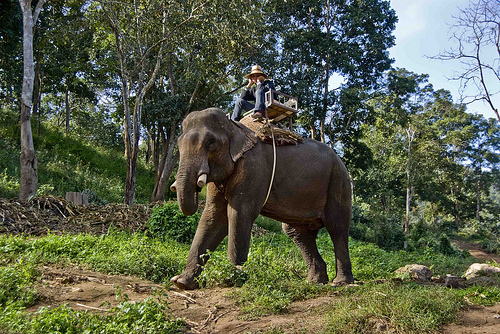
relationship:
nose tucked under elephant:
[176, 166, 198, 216] [169, 107, 352, 290]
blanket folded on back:
[239, 113, 306, 153] [233, 112, 342, 167]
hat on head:
[242, 63, 272, 78] [240, 71, 271, 83]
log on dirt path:
[389, 252, 498, 295] [0, 228, 499, 334]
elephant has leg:
[170, 93, 361, 295] [320, 215, 360, 286]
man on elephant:
[231, 65, 278, 121] [169, 107, 352, 290]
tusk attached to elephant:
[164, 172, 209, 191] [156, 99, 359, 286]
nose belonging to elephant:
[176, 166, 198, 216] [170, 93, 361, 295]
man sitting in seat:
[231, 65, 278, 121] [239, 87, 306, 147]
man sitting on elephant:
[231, 65, 278, 121] [94, 106, 379, 281]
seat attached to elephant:
[239, 87, 306, 147] [94, 106, 379, 281]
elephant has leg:
[170, 107, 352, 290] [216, 202, 252, 269]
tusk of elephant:
[170, 173, 208, 192] [169, 107, 352, 290]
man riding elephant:
[229, 61, 279, 124] [115, 65, 427, 320]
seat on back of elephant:
[260, 95, 295, 117] [169, 107, 352, 290]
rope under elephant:
[262, 126, 277, 207] [169, 107, 352, 290]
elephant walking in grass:
[170, 93, 361, 295] [245, 277, 375, 307]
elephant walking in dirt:
[170, 93, 361, 295] [34, 254, 498, 329]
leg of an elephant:
[172, 190, 228, 283] [166, 107, 395, 280]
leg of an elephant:
[282, 222, 327, 274] [169, 107, 352, 290]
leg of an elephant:
[323, 222, 365, 293] [149, 93, 377, 296]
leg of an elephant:
[186, 196, 228, 269] [170, 93, 361, 295]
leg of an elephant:
[226, 202, 261, 281] [183, 117, 365, 281]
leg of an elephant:
[288, 228, 328, 291] [169, 107, 352, 290]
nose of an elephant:
[174, 166, 199, 211] [170, 93, 361, 295]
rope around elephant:
[261, 137, 277, 212] [166, 101, 371, 292]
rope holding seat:
[261, 137, 277, 212] [237, 112, 302, 143]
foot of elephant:
[162, 270, 202, 290] [169, 107, 352, 290]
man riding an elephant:
[231, 65, 278, 121] [169, 107, 352, 290]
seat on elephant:
[239, 87, 306, 147] [173, 103, 235, 215]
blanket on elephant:
[239, 116, 305, 147] [173, 103, 235, 215]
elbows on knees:
[253, 75, 270, 88] [249, 89, 269, 94]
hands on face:
[254, 72, 265, 82] [247, 62, 268, 84]